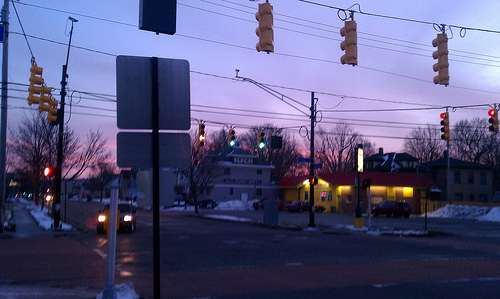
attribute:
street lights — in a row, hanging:
[250, 0, 452, 88]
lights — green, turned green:
[227, 128, 271, 147]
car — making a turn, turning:
[97, 202, 137, 237]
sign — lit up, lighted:
[317, 190, 328, 200]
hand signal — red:
[43, 165, 52, 178]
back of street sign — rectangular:
[114, 52, 192, 133]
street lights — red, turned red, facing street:
[437, 108, 500, 138]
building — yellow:
[278, 171, 428, 218]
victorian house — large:
[369, 145, 495, 206]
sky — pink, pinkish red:
[0, 1, 498, 184]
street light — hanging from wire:
[251, 4, 276, 56]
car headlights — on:
[97, 210, 132, 226]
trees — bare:
[9, 105, 111, 232]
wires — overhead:
[8, 0, 498, 105]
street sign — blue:
[429, 187, 443, 195]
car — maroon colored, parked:
[369, 199, 413, 222]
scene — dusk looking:
[1, 1, 500, 295]